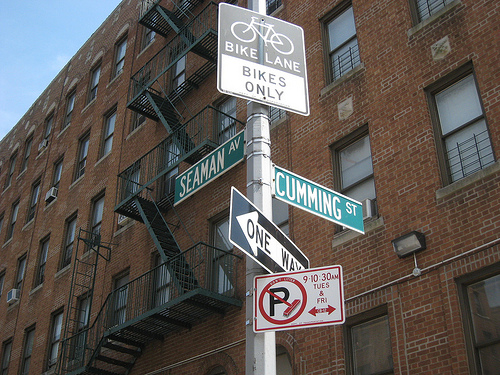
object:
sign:
[219, 1, 311, 117]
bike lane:
[224, 41, 301, 73]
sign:
[253, 264, 348, 333]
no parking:
[260, 274, 307, 326]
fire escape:
[58, 1, 246, 374]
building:
[1, 1, 499, 371]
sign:
[227, 184, 310, 274]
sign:
[274, 162, 365, 234]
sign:
[172, 128, 246, 207]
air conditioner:
[44, 187, 58, 203]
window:
[328, 122, 384, 228]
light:
[390, 231, 426, 260]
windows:
[454, 268, 498, 374]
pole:
[244, 2, 277, 374]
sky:
[0, 0, 68, 71]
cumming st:
[275, 171, 358, 221]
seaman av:
[178, 135, 244, 197]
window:
[432, 72, 497, 182]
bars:
[330, 50, 357, 68]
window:
[325, 8, 368, 81]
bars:
[452, 137, 491, 170]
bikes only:
[240, 64, 287, 101]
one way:
[246, 217, 304, 271]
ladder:
[57, 227, 102, 372]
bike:
[231, 14, 294, 56]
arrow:
[235, 211, 304, 271]